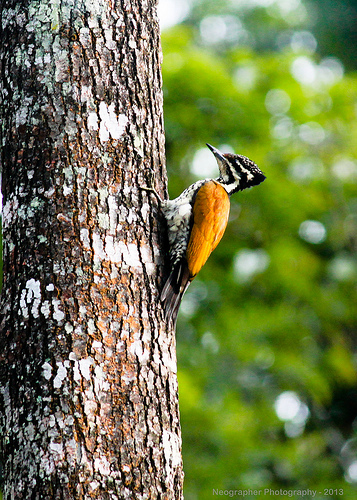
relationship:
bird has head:
[140, 141, 267, 326] [204, 141, 265, 192]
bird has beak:
[140, 141, 267, 326] [196, 135, 230, 167]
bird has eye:
[140, 141, 267, 326] [230, 154, 236, 164]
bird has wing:
[138, 117, 326, 308] [178, 178, 231, 281]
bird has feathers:
[140, 141, 267, 326] [162, 195, 192, 221]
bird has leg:
[140, 141, 267, 326] [136, 169, 165, 205]